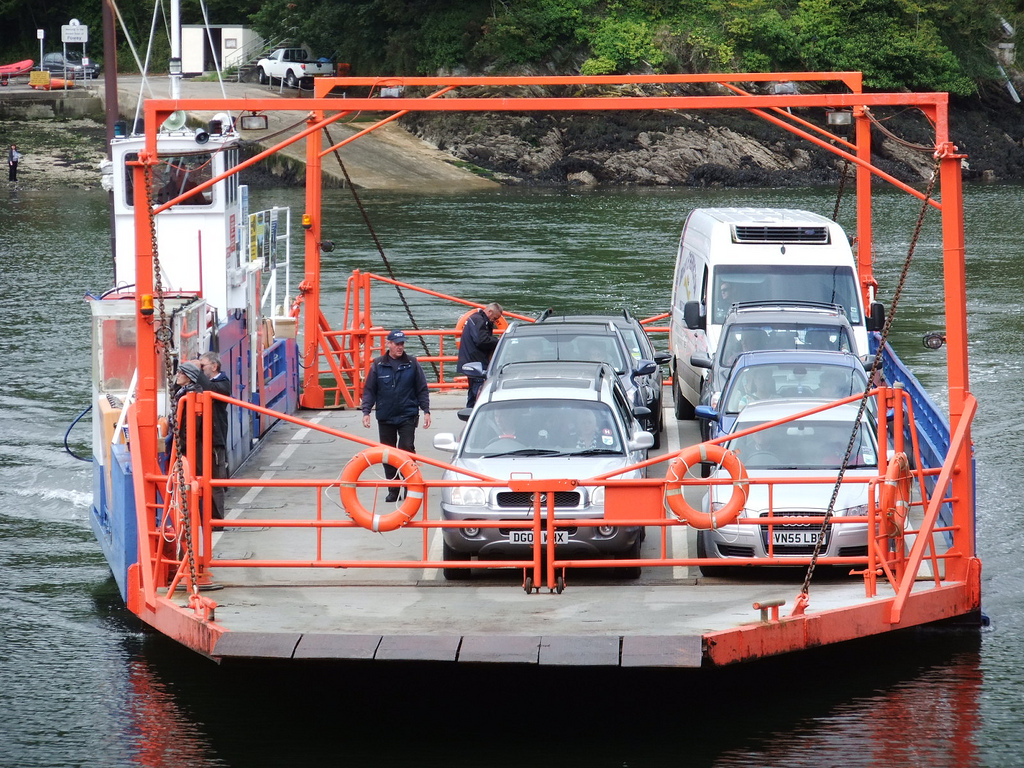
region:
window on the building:
[721, 353, 854, 411]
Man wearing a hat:
[383, 318, 416, 348]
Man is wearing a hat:
[378, 320, 417, 347]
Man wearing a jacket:
[354, 349, 434, 427]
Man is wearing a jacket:
[354, 351, 435, 431]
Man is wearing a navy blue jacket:
[356, 349, 436, 426]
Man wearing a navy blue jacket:
[354, 345, 435, 422]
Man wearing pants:
[373, 400, 428, 496]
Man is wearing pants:
[368, 412, 426, 489]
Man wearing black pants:
[370, 405, 422, 494]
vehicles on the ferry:
[433, 190, 921, 589]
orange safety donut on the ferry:
[334, 436, 429, 539]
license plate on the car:
[768, 525, 833, 554]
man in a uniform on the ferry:
[351, 309, 440, 447]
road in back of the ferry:
[365, 145, 442, 188]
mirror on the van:
[683, 293, 706, 335]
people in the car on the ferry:
[466, 399, 616, 456]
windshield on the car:
[747, 366, 859, 399]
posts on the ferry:
[851, 98, 957, 266]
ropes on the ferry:
[861, 104, 929, 282]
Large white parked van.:
[664, 210, 887, 420]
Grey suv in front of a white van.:
[684, 305, 882, 476]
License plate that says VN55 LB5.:
[764, 529, 828, 546]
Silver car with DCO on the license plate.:
[432, 388, 658, 581]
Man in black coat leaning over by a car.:
[461, 300, 500, 405]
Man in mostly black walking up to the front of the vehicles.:
[356, 330, 432, 502]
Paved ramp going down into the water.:
[93, 78, 499, 186]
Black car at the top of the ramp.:
[38, 53, 100, 80]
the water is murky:
[8, 605, 202, 743]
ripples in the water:
[21, 427, 88, 535]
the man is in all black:
[367, 329, 425, 488]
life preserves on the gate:
[343, 444, 752, 534]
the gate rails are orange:
[191, 406, 913, 580]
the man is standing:
[362, 324, 427, 474]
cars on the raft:
[472, 239, 875, 563]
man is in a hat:
[386, 332, 410, 367]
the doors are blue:
[219, 339, 264, 472]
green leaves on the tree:
[822, 19, 877, 71]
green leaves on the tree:
[932, 57, 970, 106]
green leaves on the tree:
[571, 46, 636, 114]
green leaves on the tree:
[642, 24, 690, 81]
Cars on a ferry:
[476, 170, 894, 562]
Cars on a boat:
[422, 211, 876, 605]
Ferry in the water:
[88, 70, 999, 700]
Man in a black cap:
[329, 306, 451, 502]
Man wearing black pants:
[343, 326, 445, 498]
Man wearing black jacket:
[445, 294, 503, 403]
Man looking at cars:
[312, 322, 455, 518]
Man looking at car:
[340, 326, 459, 520]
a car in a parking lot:
[464, 318, 657, 418]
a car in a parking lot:
[658, 204, 873, 420]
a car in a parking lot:
[247, 46, 331, 89]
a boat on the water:
[85, 59, 972, 717]